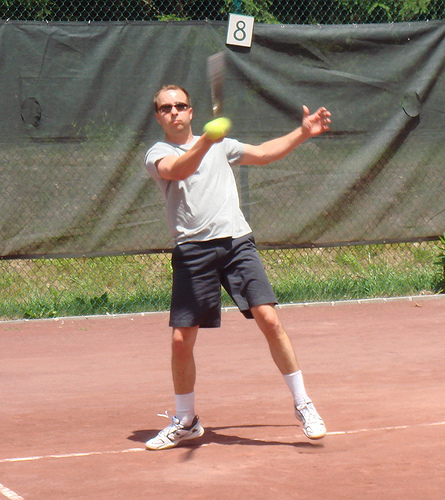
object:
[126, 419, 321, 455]
shadow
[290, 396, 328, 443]
shoe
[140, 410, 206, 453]
shoe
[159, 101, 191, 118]
goggles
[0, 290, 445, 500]
chalk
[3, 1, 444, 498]
court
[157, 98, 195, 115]
sunglasses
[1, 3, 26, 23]
mesh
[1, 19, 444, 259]
cloth background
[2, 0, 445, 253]
fence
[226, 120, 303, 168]
arms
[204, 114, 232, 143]
ball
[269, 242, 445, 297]
grass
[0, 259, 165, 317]
grass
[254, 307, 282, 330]
knee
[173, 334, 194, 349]
knee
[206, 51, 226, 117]
racket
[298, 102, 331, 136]
hand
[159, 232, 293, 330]
shorts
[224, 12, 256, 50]
card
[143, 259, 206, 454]
leg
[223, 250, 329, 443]
leg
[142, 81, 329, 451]
he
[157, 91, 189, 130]
face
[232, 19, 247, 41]
number 8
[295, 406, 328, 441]
foot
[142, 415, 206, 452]
foot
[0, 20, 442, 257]
tarp